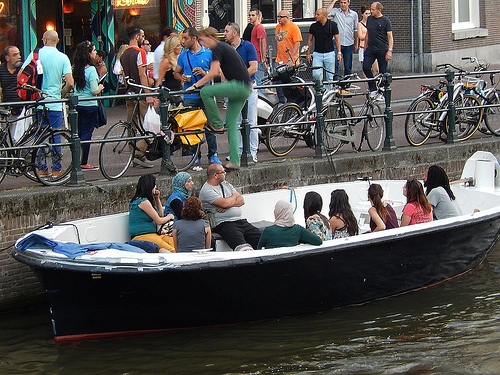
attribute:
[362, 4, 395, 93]
person — outdoors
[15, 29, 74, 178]
person — outdoors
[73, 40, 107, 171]
person — outdoors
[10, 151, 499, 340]
boat — small, black, white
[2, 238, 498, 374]
water — murky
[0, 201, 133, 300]
wall — brick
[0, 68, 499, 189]
railing — long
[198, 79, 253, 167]
pants — green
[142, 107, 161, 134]
bag — plastic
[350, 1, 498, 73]
building — red brick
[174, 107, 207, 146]
bag — yellow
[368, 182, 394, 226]
hairstyle — ponytail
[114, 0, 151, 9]
sign — neon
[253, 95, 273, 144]
scooter — motor scooter